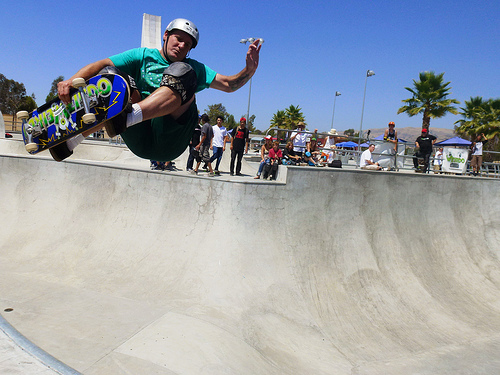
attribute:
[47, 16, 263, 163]
man — mid air, skateboarding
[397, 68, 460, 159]
tree — green, palm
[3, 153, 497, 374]
pool — skateboard, concrete, empty, large, cement, curved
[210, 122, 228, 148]
t-shirt — white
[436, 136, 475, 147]
umbrella — large, blue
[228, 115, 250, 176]
man — in black, red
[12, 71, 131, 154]
skateboard — white, blue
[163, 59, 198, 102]
kneepad — black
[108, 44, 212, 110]
shirt — aqua, green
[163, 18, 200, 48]
helmet — gray, safety, silver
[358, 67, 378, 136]
lightposts — tall, background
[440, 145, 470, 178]
sign — small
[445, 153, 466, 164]
text — gren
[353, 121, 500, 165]
hills — distance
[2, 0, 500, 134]
sky — cloudless, blue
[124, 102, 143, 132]
sock — white